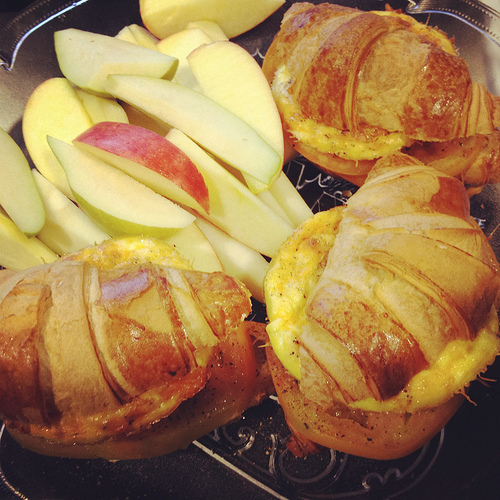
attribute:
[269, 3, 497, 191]
croissant sandwich — cooking, cut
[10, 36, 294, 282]
apples — sliced, yellow, cut, green, red, small, bunched, white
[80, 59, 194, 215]
skin — red, green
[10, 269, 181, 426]
bacon — cooked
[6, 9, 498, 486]
platter — round, grated, black, metallic, shiny, glass, serving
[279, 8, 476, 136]
top — baked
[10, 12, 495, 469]
sandwiches — croissants, cut